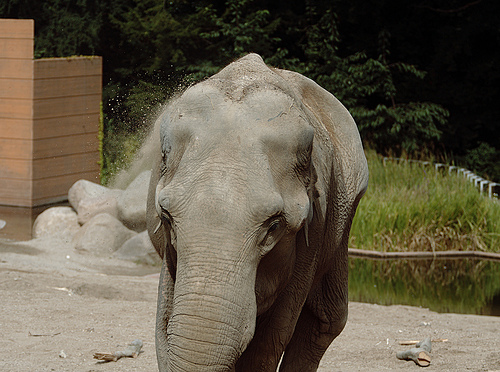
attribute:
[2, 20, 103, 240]
wall — wood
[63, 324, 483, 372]
dirt — large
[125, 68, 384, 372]
elephant — big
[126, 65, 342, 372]
elephant — large, gray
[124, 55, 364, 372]
elephant — gray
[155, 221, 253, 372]
trunk — large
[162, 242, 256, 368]
trunk — large, gray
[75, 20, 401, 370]
elephant — large, gray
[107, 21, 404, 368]
elephant — gray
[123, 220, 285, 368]
trunk — large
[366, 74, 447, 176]
leaves — green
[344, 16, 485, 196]
leaves — green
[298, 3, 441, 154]
leaves — green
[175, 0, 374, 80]
leaves — green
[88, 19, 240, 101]
leaves — green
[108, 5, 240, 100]
leaves — green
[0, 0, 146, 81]
leaves — green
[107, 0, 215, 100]
leaves — green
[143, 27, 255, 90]
leaves — green